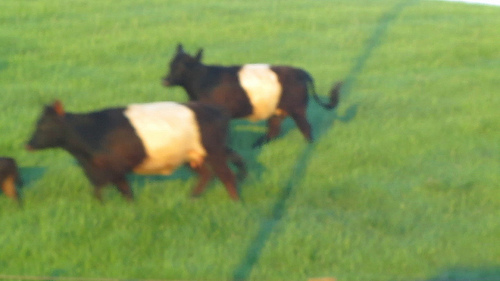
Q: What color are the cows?
A: The cows are black and white.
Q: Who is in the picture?
A: Nobody but cows are in the picture.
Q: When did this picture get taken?
A: It was taken in the day time.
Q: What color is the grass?
A: The grass is green.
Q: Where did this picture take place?
A: It took place in a field.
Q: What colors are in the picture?
A: The colors green,black, and white are in the pictures.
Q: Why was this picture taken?
A: To show how the cows look.